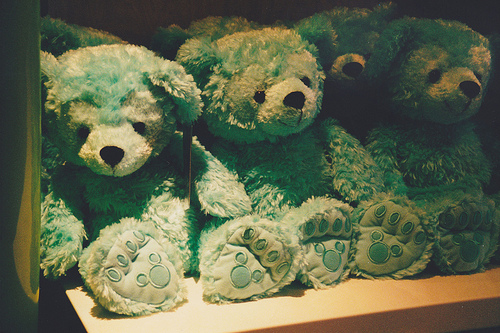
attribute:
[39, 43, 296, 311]
teddy bear — blue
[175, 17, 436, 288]
teddy bear — blue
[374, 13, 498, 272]
teddy bear — blue